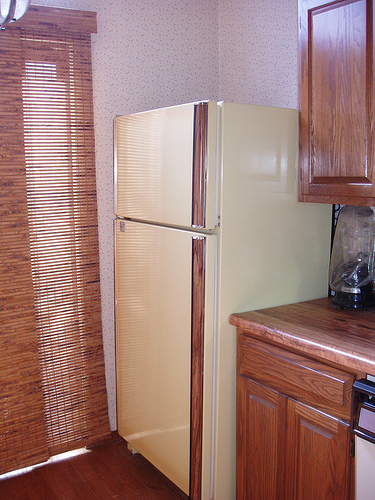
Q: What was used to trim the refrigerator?
A: Wood.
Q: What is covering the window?
A: Wooden blinds.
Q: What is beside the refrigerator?
A: Wooden cabinets.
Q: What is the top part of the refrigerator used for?
A: Frozen food.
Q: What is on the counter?
A: A black blender.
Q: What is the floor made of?
A: Wood.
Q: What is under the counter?
A: Wooden cabinets.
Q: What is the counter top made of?
A: Wood.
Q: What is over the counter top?
A: An upper cabinet.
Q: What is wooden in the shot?
A: Two cabinet doors.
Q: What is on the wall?
A: The wallpaper.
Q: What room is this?
A: A kitchen.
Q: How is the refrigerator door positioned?
A: Closed.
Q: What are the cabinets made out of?
A: Wood.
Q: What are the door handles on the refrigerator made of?
A: Wood.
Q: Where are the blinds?
A: On the window.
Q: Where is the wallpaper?
A: On the wall.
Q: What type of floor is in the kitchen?
A: Hardwood.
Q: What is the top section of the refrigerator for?
A: Freezing food.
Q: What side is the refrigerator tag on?
A: The left side.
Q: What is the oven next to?
A: The cabinets.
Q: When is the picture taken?
A: Day time.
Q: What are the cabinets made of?
A: Wood.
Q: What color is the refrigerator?
A: Tan.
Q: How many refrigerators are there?
A: One.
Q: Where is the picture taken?
A: Kitchen.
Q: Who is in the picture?
A: No one.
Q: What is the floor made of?
A: Wood.